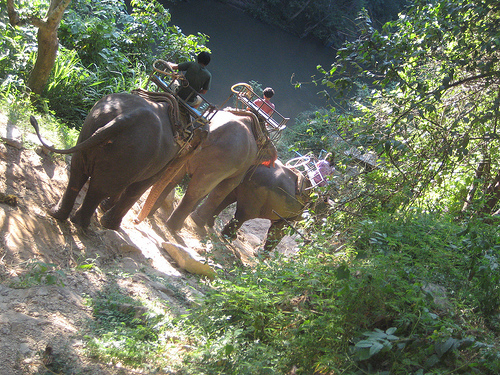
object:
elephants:
[150, 113, 278, 231]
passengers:
[242, 88, 277, 123]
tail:
[28, 114, 132, 153]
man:
[170, 52, 211, 108]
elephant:
[29, 89, 210, 230]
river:
[120, 5, 387, 127]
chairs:
[233, 84, 289, 154]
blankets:
[225, 106, 277, 168]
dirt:
[1, 135, 302, 373]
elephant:
[208, 159, 327, 262]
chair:
[145, 61, 218, 138]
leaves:
[354, 335, 372, 348]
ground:
[0, 106, 320, 374]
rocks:
[162, 242, 218, 281]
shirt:
[177, 63, 211, 102]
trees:
[0, 0, 110, 102]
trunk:
[0, 1, 73, 107]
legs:
[99, 171, 164, 231]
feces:
[0, 190, 20, 208]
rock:
[1, 126, 22, 148]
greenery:
[0, 1, 498, 374]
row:
[29, 88, 338, 257]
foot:
[46, 203, 68, 221]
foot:
[70, 209, 89, 224]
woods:
[270, 56, 499, 375]